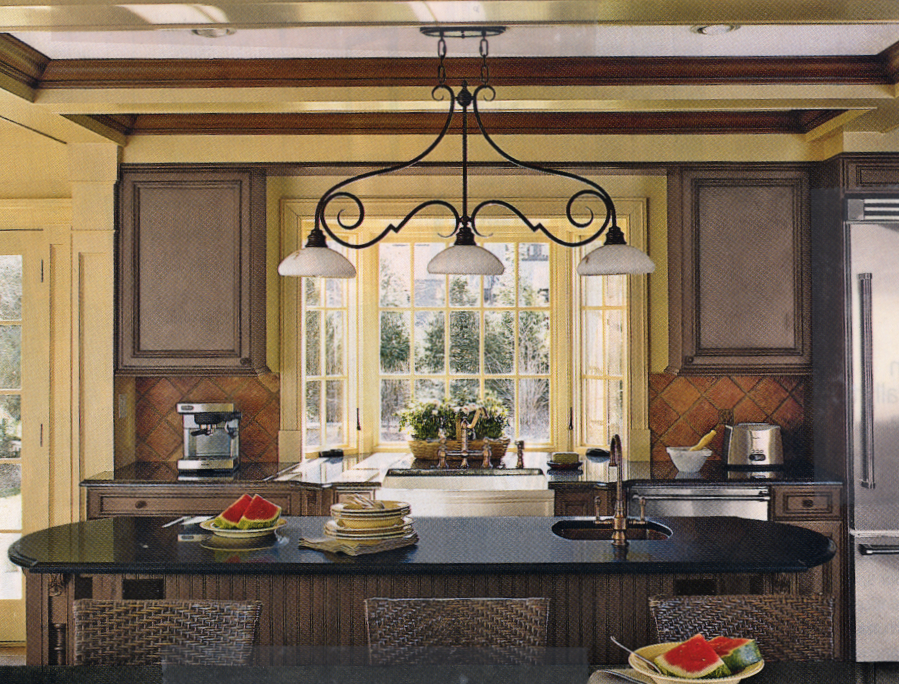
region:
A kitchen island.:
[12, 486, 855, 674]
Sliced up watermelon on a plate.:
[183, 484, 299, 563]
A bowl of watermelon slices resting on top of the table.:
[599, 624, 774, 681]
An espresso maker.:
[175, 399, 241, 468]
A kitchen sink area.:
[392, 420, 555, 477]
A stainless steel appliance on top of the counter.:
[717, 417, 792, 483]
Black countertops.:
[32, 439, 848, 577]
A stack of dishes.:
[306, 476, 429, 546]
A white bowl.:
[660, 435, 717, 478]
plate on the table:
[364, 501, 403, 511]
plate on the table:
[362, 537, 372, 539]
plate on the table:
[378, 529, 389, 535]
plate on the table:
[223, 528, 246, 534]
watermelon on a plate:
[211, 493, 280, 532]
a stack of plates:
[332, 490, 403, 538]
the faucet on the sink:
[603, 435, 624, 540]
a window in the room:
[295, 210, 616, 468]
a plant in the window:
[407, 400, 512, 443]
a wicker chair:
[60, 594, 257, 667]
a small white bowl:
[671, 436, 705, 465]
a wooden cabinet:
[116, 172, 259, 367]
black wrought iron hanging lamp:
[279, 23, 655, 279]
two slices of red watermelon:
[215, 490, 285, 532]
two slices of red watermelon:
[648, 632, 763, 675]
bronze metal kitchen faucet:
[604, 433, 632, 540]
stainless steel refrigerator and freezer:
[813, 195, 896, 666]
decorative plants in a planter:
[409, 404, 511, 461]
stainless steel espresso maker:
[176, 397, 237, 483]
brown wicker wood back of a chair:
[62, 599, 261, 660]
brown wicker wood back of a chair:
[363, 597, 553, 650]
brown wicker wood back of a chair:
[645, 588, 838, 661]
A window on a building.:
[409, 242, 451, 308]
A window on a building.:
[446, 236, 481, 306]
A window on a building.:
[511, 233, 552, 301]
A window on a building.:
[514, 304, 551, 378]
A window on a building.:
[478, 301, 521, 378]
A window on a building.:
[446, 309, 483, 378]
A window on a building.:
[406, 306, 450, 370]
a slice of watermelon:
[237, 486, 279, 523]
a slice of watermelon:
[656, 629, 727, 677]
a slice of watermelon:
[712, 632, 768, 673]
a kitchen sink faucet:
[591, 432, 648, 550]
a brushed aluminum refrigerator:
[813, 190, 896, 660]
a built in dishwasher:
[628, 482, 771, 523]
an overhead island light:
[278, 21, 662, 276]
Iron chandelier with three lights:
[276, 26, 654, 273]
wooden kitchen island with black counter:
[3, 516, 833, 673]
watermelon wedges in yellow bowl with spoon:
[611, 629, 765, 680]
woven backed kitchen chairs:
[68, 589, 839, 662]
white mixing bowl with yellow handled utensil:
[665, 426, 718, 476]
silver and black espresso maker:
[174, 399, 243, 474]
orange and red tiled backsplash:
[133, 366, 809, 463]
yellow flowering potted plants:
[395, 388, 510, 463]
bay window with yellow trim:
[279, 195, 646, 463]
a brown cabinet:
[114, 173, 259, 366]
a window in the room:
[303, 223, 627, 459]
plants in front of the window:
[411, 402, 506, 453]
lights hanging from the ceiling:
[284, 171, 652, 286]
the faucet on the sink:
[584, 434, 643, 526]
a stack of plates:
[326, 492, 406, 540]